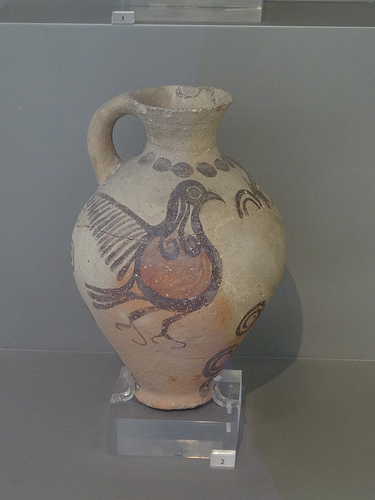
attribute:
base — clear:
[110, 363, 242, 461]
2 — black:
[218, 458, 227, 466]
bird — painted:
[81, 179, 227, 350]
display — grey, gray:
[0, 22, 373, 499]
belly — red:
[135, 231, 223, 309]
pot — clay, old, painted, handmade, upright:
[70, 86, 288, 410]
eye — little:
[185, 185, 203, 199]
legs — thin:
[114, 305, 191, 352]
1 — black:
[121, 14, 126, 22]